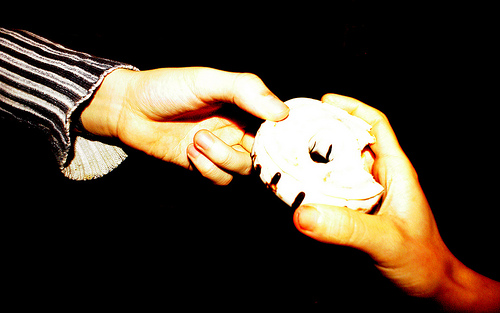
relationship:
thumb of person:
[202, 64, 292, 107] [5, 9, 310, 185]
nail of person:
[269, 91, 303, 116] [5, 9, 310, 185]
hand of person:
[114, 56, 283, 211] [5, 9, 310, 185]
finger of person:
[181, 133, 259, 186] [5, 9, 310, 185]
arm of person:
[0, 25, 188, 191] [5, 9, 310, 185]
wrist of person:
[33, 39, 155, 189] [5, 9, 310, 185]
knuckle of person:
[351, 78, 421, 249] [5, 9, 310, 185]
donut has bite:
[236, 93, 397, 213] [342, 112, 376, 209]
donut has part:
[236, 93, 397, 213] [332, 118, 390, 191]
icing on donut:
[299, 120, 354, 192] [236, 93, 397, 213]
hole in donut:
[286, 116, 346, 172] [236, 93, 397, 213]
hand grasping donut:
[114, 56, 283, 211] [250, 96, 384, 213]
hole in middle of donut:
[236, 93, 397, 213] [250, 96, 384, 213]